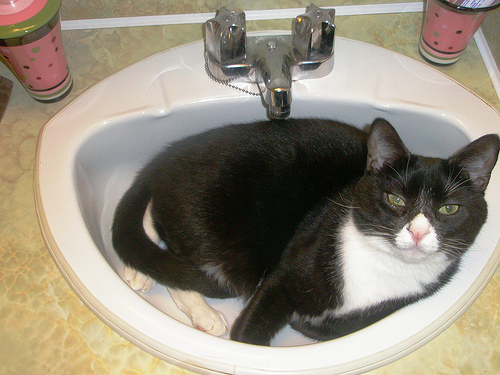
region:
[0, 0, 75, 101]
a colorful cup on a counter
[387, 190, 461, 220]
a cat with green eyes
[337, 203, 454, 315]
a black cat with white fur on its chest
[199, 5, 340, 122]
a stainless steel faucet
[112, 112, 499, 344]
a cat laying in a sink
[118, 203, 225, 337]
white paws of a black cat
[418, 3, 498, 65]
a pink glass with lines and dots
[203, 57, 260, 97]
a metal chain on a faucet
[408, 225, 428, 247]
pink nose of a cat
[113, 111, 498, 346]
a black and white cat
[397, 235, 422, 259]
part of a mouth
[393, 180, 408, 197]
part of an eylid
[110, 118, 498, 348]
Black and white cat laying in sink.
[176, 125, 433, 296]
this is a cat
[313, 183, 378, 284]
the cat is white and back in color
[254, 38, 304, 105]
this is a tap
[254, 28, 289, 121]
the tap is metallic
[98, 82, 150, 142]
this is the sink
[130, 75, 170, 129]
the sink is white in color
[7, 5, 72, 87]
this is a tin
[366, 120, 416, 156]
this is the ear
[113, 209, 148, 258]
this is the tail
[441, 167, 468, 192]
this is the fur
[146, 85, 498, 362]
the cat is black in colour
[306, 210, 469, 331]
it has a white patch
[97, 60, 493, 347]
the cat is on the sink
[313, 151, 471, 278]
its eyes are open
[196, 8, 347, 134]
the tap is silver in colour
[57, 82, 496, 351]
the sink is white in colour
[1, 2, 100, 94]
the cup is pink in colour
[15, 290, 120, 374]
the surface is brown in colour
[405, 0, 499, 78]
the cup is decorated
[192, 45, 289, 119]
a chain is on the tap